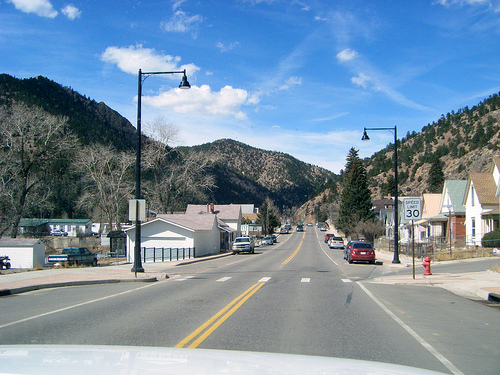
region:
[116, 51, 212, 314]
street light over road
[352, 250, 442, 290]
red fire hydrant on corner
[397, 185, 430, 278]
speed limit sign on pole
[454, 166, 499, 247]
white house with brown roof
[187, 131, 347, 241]
big mountains along road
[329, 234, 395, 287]
red car parked at curb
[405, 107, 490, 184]
trees on the mountainside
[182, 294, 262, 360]
double yellow line painted on road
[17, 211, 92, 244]
white house with green roof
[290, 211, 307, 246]
vehicle driving up road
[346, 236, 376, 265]
red vehicle parked on road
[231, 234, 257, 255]
white vehicle parked on road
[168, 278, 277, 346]
double yellow lines painted on road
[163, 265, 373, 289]
white cross walk lines painted on road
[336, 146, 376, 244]
large green tree on ground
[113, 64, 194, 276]
tall lamp post on sidewalk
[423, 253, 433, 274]
red fire hydrant on sidewalk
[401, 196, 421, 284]
white traffic sign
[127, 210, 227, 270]
white building with slanted roof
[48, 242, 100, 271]
pickup truck colored white and blue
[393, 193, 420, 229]
speed limit sign on road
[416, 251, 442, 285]
red fire hydrant on road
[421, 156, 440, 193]
evergreen tree on mountain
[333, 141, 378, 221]
evergreen tree on mountain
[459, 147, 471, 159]
evergreen tree on mountain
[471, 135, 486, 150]
evergreen tree on mountain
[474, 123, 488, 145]
evergreen tree on mountain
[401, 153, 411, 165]
evergreen tree on mountain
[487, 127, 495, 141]
evergreen tree on mountain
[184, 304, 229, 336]
yellow line in road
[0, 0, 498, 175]
a cloudy blue sky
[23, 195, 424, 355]
a long paved road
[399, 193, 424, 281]
a speed limit sign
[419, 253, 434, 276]
a red fire hydrant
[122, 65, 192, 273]
a tall street light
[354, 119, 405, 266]
a tall street light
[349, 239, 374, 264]
a parked red car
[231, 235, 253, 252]
a white parked truck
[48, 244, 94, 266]
a dark colored pick up truck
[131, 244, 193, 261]
a long metal fence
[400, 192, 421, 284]
speed limit sign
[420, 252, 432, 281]
red fire hydrant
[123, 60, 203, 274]
the street light with a backwards sign on the pole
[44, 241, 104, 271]
a blue and white pick-up truck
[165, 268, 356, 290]
the white lines of the crosswalk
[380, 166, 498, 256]
a row of homes on the right side of the street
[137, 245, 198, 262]
a fence on the left side of the street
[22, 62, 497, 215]
three mountains with green trees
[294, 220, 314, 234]
cars driving on the street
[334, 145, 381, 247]
a tall evergreen tree